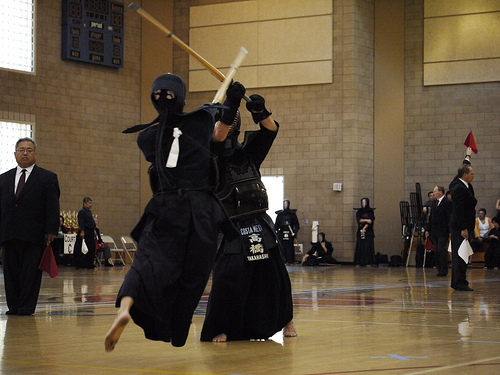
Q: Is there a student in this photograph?
A: No, there are no students.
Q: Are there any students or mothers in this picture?
A: No, there are no students or mothers.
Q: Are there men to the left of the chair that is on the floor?
A: Yes, there is a man to the left of the chair.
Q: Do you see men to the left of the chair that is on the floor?
A: Yes, there is a man to the left of the chair.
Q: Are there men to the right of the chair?
A: No, the man is to the left of the chair.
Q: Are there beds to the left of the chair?
A: No, there is a man to the left of the chair.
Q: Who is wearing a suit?
A: The man is wearing a suit.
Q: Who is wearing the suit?
A: The man is wearing a suit.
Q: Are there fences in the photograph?
A: No, there are no fences.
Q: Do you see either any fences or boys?
A: No, there are no fences or boys.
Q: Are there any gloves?
A: Yes, there are gloves.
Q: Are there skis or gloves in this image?
A: Yes, there are gloves.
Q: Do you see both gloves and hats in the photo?
A: No, there are gloves but no hats.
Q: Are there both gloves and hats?
A: No, there are gloves but no hats.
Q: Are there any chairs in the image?
A: Yes, there is a chair.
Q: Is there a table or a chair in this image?
A: Yes, there is a chair.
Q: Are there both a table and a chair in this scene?
A: Yes, there are both a chair and a table.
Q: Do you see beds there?
A: No, there are no beds.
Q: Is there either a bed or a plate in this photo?
A: No, there are no beds or plates.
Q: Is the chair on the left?
A: Yes, the chair is on the left of the image.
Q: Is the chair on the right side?
A: No, the chair is on the left of the image.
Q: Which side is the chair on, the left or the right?
A: The chair is on the left of the image.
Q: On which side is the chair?
A: The chair is on the left of the image.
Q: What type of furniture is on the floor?
A: The piece of furniture is a chair.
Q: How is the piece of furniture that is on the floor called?
A: The piece of furniture is a chair.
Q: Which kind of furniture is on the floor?
A: The piece of furniture is a chair.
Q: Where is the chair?
A: The chair is on the floor.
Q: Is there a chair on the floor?
A: Yes, there is a chair on the floor.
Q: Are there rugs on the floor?
A: No, there is a chair on the floor.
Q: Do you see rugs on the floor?
A: No, there is a chair on the floor.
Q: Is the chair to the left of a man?
A: No, the chair is to the right of a man.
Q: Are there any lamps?
A: No, there are no lamps.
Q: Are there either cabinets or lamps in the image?
A: No, there are no lamps or cabinets.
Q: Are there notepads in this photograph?
A: No, there are no notepads.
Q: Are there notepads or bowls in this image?
A: No, there are no notepads or bowls.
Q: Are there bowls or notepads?
A: No, there are no notepads or bowls.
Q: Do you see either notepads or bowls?
A: No, there are no notepads or bowls.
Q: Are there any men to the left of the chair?
A: Yes, there is a man to the left of the chair.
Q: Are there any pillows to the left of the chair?
A: No, there is a man to the left of the chair.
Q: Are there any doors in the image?
A: Yes, there is a door.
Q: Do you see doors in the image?
A: Yes, there is a door.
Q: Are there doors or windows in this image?
A: Yes, there is a door.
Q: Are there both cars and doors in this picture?
A: No, there is a door but no cars.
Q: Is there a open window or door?
A: Yes, there is an open door.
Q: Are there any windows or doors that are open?
A: Yes, the door is open.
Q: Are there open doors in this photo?
A: Yes, there is an open door.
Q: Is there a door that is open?
A: Yes, there is a door that is open.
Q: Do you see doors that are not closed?
A: Yes, there is a open door.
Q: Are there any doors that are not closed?
A: Yes, there is a open door.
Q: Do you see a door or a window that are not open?
A: No, there is a door but it is open.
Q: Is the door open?
A: Yes, the door is open.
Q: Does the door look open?
A: Yes, the door is open.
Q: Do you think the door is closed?
A: No, the door is open.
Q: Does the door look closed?
A: No, the door is open.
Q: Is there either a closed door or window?
A: No, there is a door but it is open.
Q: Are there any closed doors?
A: No, there is a door but it is open.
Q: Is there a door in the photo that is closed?
A: No, there is a door but it is open.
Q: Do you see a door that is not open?
A: No, there is a door but it is open.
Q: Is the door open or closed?
A: The door is open.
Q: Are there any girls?
A: No, there are no girls.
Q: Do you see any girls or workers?
A: No, there are no girls or workers.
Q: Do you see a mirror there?
A: No, there are no mirrors.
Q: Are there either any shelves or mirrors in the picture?
A: No, there are no mirrors or shelves.